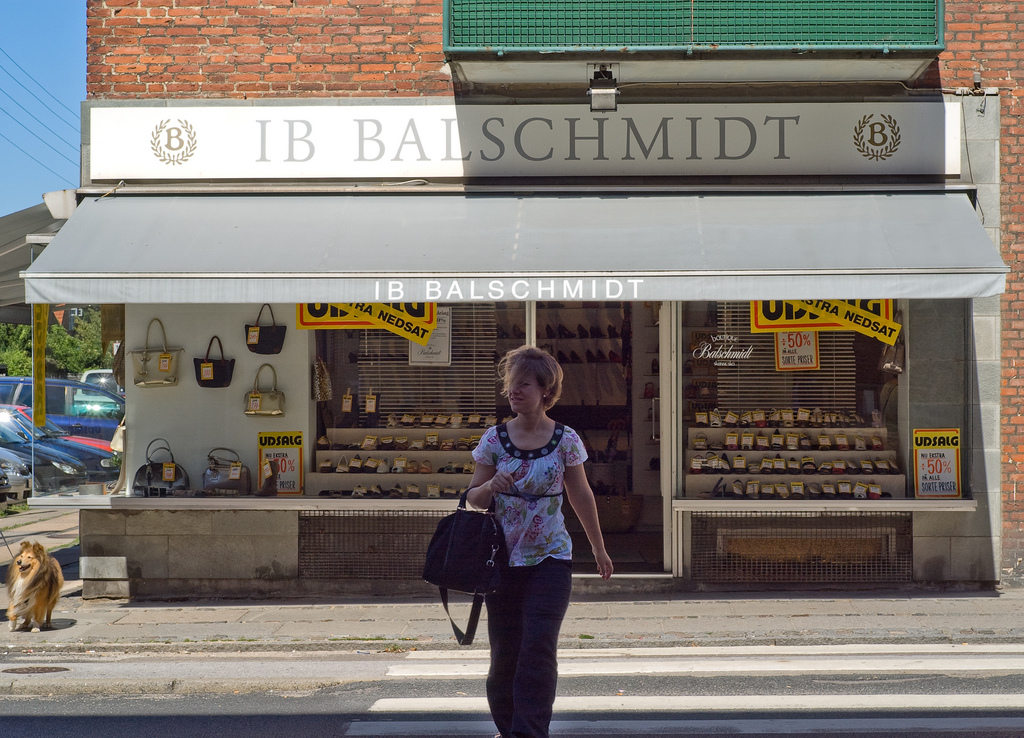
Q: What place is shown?
A: It is a display.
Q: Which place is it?
A: It is a display.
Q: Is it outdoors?
A: Yes, it is outdoors.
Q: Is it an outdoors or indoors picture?
A: It is outdoors.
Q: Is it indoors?
A: No, it is outdoors.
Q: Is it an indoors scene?
A: No, it is outdoors.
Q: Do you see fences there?
A: No, there are no fences.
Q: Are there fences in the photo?
A: No, there are no fences.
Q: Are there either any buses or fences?
A: No, there are no fences or buses.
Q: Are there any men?
A: No, there are no men.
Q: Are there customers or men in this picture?
A: No, there are no men or customers.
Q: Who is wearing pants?
A: The lady is wearing pants.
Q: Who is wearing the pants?
A: The lady is wearing pants.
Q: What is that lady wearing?
A: The lady is wearing pants.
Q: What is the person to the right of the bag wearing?
A: The lady is wearing pants.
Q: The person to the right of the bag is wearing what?
A: The lady is wearing pants.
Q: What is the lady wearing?
A: The lady is wearing pants.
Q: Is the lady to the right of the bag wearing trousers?
A: Yes, the lady is wearing trousers.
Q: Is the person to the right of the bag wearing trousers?
A: Yes, the lady is wearing trousers.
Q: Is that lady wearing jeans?
A: No, the lady is wearing trousers.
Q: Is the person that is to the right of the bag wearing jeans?
A: No, the lady is wearing trousers.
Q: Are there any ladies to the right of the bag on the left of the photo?
A: Yes, there is a lady to the right of the bag.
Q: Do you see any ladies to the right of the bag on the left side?
A: Yes, there is a lady to the right of the bag.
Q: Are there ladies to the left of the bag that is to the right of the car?
A: No, the lady is to the right of the bag.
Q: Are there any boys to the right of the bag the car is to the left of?
A: No, there is a lady to the right of the bag.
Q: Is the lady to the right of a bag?
A: Yes, the lady is to the right of a bag.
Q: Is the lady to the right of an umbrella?
A: No, the lady is to the right of a bag.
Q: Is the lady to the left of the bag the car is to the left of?
A: No, the lady is to the right of the bag.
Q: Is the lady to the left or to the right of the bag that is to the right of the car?
A: The lady is to the right of the bag.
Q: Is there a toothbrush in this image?
A: No, there are no toothbrushes.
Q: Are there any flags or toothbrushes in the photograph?
A: No, there are no toothbrushes or flags.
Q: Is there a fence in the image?
A: No, there are no fences.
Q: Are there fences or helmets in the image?
A: No, there are no fences or helmets.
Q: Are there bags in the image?
A: Yes, there is a bag.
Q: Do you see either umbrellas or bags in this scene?
A: Yes, there is a bag.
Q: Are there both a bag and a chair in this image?
A: No, there is a bag but no chairs.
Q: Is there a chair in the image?
A: No, there are no chairs.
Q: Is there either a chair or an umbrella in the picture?
A: No, there are no chairs or umbrellas.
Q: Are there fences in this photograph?
A: No, there are no fences.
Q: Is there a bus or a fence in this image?
A: No, there are no fences or buses.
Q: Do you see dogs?
A: Yes, there is a dog.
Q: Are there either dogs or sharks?
A: Yes, there is a dog.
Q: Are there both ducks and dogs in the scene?
A: No, there is a dog but no ducks.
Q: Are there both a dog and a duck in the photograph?
A: No, there is a dog but no ducks.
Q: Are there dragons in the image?
A: No, there are no dragons.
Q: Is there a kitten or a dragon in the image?
A: No, there are no dragons or kittens.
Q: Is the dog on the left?
A: Yes, the dog is on the left of the image.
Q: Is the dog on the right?
A: No, the dog is on the left of the image.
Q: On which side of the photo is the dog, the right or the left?
A: The dog is on the left of the image.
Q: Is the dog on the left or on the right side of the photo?
A: The dog is on the left of the image.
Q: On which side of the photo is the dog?
A: The dog is on the left of the image.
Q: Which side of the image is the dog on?
A: The dog is on the left of the image.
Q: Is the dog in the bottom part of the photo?
A: Yes, the dog is in the bottom of the image.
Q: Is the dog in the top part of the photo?
A: No, the dog is in the bottom of the image.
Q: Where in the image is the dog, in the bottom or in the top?
A: The dog is in the bottom of the image.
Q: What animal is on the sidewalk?
A: The animal is a dog.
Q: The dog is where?
A: The dog is on the side walk.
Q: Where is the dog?
A: The dog is on the side walk.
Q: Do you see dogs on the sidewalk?
A: Yes, there is a dog on the sidewalk.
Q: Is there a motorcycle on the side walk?
A: No, there is a dog on the side walk.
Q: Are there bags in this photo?
A: Yes, there is a bag.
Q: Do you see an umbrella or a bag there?
A: Yes, there is a bag.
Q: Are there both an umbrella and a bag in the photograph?
A: No, there is a bag but no umbrellas.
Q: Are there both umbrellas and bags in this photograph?
A: No, there is a bag but no umbrellas.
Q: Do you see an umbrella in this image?
A: No, there are no umbrellas.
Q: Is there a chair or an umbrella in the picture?
A: No, there are no umbrellas or chairs.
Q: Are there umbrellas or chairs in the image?
A: No, there are no umbrellas or chairs.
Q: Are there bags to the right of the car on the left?
A: Yes, there is a bag to the right of the car.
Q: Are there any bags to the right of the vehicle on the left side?
A: Yes, there is a bag to the right of the car.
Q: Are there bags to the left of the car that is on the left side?
A: No, the bag is to the right of the car.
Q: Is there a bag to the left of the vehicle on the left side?
A: No, the bag is to the right of the car.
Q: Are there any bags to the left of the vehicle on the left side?
A: No, the bag is to the right of the car.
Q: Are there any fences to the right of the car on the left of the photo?
A: No, there is a bag to the right of the car.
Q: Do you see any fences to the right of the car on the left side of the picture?
A: No, there is a bag to the right of the car.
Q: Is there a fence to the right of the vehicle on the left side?
A: No, there is a bag to the right of the car.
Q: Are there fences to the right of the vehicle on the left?
A: No, there is a bag to the right of the car.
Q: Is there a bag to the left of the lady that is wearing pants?
A: Yes, there is a bag to the left of the lady.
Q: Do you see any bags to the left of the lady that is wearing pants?
A: Yes, there is a bag to the left of the lady.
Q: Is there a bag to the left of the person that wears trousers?
A: Yes, there is a bag to the left of the lady.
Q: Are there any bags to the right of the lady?
A: No, the bag is to the left of the lady.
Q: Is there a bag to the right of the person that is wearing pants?
A: No, the bag is to the left of the lady.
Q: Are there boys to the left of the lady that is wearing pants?
A: No, there is a bag to the left of the lady.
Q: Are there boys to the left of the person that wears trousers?
A: No, there is a bag to the left of the lady.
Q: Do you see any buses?
A: No, there are no buses.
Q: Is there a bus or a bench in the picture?
A: No, there are no buses or benches.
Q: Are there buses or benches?
A: No, there are no buses or benches.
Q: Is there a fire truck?
A: No, there are no fire trucks.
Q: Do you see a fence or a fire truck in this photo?
A: No, there are no fire trucks or fences.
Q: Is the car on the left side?
A: Yes, the car is on the left of the image.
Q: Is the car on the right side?
A: No, the car is on the left of the image.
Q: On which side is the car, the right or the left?
A: The car is on the left of the image.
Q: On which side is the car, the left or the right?
A: The car is on the left of the image.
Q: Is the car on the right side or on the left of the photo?
A: The car is on the left of the image.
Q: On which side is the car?
A: The car is on the left of the image.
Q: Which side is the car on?
A: The car is on the left of the image.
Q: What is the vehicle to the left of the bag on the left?
A: The vehicle is a car.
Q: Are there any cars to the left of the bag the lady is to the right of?
A: Yes, there is a car to the left of the bag.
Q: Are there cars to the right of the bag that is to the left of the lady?
A: No, the car is to the left of the bag.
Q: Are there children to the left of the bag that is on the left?
A: No, there is a car to the left of the bag.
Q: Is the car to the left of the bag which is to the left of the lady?
A: Yes, the car is to the left of the bag.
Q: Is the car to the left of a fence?
A: No, the car is to the left of the bag.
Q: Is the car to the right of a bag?
A: No, the car is to the left of a bag.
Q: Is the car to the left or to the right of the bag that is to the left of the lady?
A: The car is to the left of the bag.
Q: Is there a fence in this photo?
A: No, there are no fences.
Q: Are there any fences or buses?
A: No, there are no fences or buses.